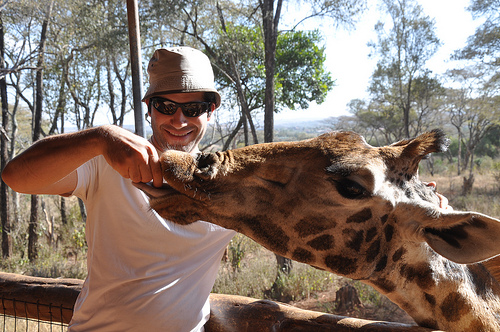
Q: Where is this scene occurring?
A: A wildlife park.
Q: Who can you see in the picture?
A: A man.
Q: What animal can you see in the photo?
A: A giraffe.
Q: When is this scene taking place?
A: Mid afternoon.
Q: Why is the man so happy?
A: Giraffe is eating out of his hand.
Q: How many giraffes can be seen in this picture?
A: 1.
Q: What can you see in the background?
A: Trees.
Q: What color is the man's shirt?
A: White.